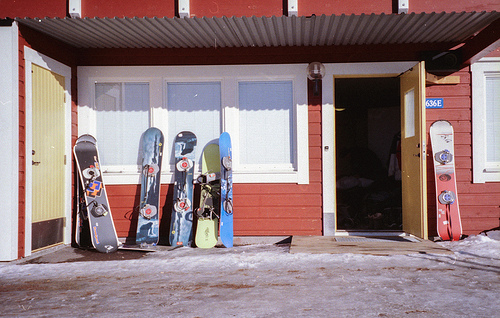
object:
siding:
[253, 191, 315, 230]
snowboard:
[213, 130, 240, 248]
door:
[322, 59, 432, 237]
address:
[424, 99, 444, 111]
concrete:
[145, 290, 321, 315]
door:
[33, 66, 72, 239]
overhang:
[171, 12, 336, 48]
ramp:
[289, 231, 445, 255]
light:
[303, 61, 327, 97]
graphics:
[83, 160, 104, 199]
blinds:
[237, 80, 294, 167]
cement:
[203, 258, 388, 316]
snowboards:
[70, 142, 121, 253]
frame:
[318, 61, 341, 242]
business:
[77, 42, 500, 241]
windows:
[94, 80, 151, 173]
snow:
[460, 231, 498, 254]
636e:
[424, 97, 446, 109]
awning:
[16, 7, 500, 53]